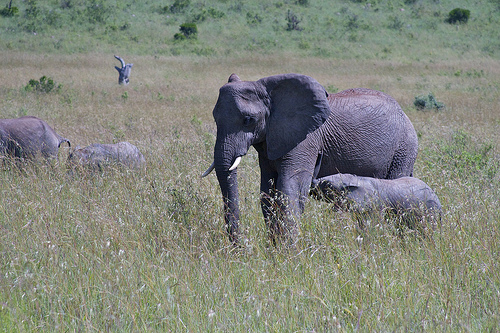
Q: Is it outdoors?
A: Yes, it is outdoors.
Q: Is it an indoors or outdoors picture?
A: It is outdoors.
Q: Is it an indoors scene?
A: No, it is outdoors.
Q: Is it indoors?
A: No, it is outdoors.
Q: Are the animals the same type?
A: Yes, all the animals are elephants.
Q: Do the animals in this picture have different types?
A: No, all the animals are elephants.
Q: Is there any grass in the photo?
A: Yes, there is grass.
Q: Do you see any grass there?
A: Yes, there is grass.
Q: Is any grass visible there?
A: Yes, there is grass.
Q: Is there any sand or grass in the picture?
A: Yes, there is grass.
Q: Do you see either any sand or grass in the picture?
A: Yes, there is grass.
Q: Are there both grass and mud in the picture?
A: No, there is grass but no mud.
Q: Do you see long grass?
A: Yes, there is long grass.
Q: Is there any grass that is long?
A: Yes, there is grass that is long.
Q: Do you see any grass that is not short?
A: Yes, there is long grass.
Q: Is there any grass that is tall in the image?
A: Yes, there is tall grass.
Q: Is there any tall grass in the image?
A: Yes, there is tall grass.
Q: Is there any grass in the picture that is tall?
A: Yes, there is grass that is tall.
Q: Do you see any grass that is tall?
A: Yes, there is grass that is tall.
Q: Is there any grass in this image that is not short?
A: Yes, there is tall grass.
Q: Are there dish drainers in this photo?
A: No, there are no dish drainers.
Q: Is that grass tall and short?
A: No, the grass is tall but long.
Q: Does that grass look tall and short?
A: No, the grass is tall but long.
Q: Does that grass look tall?
A: Yes, the grass is tall.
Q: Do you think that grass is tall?
A: Yes, the grass is tall.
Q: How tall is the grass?
A: The grass is tall.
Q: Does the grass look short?
A: No, the grass is tall.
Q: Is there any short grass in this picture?
A: No, there is grass but it is tall.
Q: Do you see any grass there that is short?
A: No, there is grass but it is tall.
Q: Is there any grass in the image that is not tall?
A: No, there is grass but it is tall.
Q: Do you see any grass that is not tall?
A: No, there is grass but it is tall.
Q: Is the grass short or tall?
A: The grass is tall.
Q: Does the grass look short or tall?
A: The grass is tall.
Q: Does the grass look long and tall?
A: Yes, the grass is long and tall.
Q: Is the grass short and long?
A: No, the grass is long but tall.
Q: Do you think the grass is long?
A: Yes, the grass is long.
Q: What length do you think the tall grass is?
A: The grass is long.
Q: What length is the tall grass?
A: The grass is long.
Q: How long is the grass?
A: The grass is long.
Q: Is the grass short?
A: No, the grass is long.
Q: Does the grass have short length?
A: No, the grass is long.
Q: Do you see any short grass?
A: No, there is grass but it is long.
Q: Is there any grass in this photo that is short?
A: No, there is grass but it is long.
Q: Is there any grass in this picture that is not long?
A: No, there is grass but it is long.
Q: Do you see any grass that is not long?
A: No, there is grass but it is long.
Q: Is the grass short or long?
A: The grass is long.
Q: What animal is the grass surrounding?
A: The grass is surrounding the elephant.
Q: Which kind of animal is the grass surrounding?
A: The grass is surrounding the elephant.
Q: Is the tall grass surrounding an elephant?
A: Yes, the grass is surrounding an elephant.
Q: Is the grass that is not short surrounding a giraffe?
A: No, the grass is surrounding an elephant.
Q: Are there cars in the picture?
A: No, there are no cars.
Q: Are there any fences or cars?
A: No, there are no cars or fences.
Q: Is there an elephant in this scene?
A: Yes, there is an elephant.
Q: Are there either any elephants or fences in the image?
A: Yes, there is an elephant.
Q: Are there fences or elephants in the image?
A: Yes, there is an elephant.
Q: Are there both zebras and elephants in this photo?
A: No, there is an elephant but no zebras.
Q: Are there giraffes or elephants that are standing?
A: Yes, the elephant is standing.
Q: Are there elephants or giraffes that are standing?
A: Yes, the elephant is standing.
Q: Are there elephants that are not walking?
A: Yes, there is an elephant that is standing.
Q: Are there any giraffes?
A: No, there are no giraffes.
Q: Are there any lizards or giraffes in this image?
A: No, there are no giraffes or lizards.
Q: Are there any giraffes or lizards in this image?
A: No, there are no giraffes or lizards.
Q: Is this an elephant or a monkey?
A: This is an elephant.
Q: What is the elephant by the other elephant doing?
A: The elephant is standing.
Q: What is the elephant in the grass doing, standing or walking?
A: The elephant is standing.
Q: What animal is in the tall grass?
A: The animal is an elephant.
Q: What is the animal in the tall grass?
A: The animal is an elephant.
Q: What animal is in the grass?
A: The animal is an elephant.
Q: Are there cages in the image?
A: No, there are no cages.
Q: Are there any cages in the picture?
A: No, there are no cages.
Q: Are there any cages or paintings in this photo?
A: No, there are no cages or paintings.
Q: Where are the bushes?
A: The bushes are on the hill.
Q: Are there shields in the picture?
A: No, there are no shields.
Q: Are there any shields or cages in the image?
A: No, there are no shields or cages.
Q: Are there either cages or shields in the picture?
A: No, there are no shields or cages.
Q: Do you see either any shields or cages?
A: No, there are no shields or cages.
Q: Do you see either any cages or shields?
A: No, there are no shields or cages.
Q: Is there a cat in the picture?
A: No, there are no cats.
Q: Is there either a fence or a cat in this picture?
A: No, there are no cats or fences.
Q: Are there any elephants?
A: Yes, there are elephants.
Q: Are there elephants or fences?
A: Yes, there are elephants.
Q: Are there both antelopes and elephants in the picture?
A: No, there are elephants but no antelopes.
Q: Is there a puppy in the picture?
A: No, there are no puppies.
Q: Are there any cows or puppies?
A: No, there are no puppies or cows.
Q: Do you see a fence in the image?
A: No, there are no fences.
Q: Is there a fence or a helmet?
A: No, there are no fences or helmets.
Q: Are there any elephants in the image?
A: Yes, there is an elephant.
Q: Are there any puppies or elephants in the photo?
A: Yes, there is an elephant.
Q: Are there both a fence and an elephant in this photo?
A: No, there is an elephant but no fences.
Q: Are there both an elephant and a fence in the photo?
A: No, there is an elephant but no fences.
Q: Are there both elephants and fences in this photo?
A: No, there is an elephant but no fences.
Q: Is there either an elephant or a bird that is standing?
A: Yes, the elephant is standing.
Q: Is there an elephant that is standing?
A: Yes, there is an elephant that is standing.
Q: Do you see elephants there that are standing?
A: Yes, there is an elephant that is standing.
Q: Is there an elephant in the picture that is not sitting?
A: Yes, there is an elephant that is standing.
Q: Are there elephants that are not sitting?
A: Yes, there is an elephant that is standing.